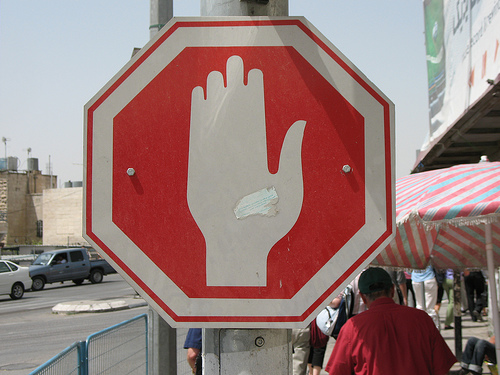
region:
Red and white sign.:
[66, 13, 401, 343]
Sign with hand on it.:
[89, 6, 419, 327]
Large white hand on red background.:
[182, 55, 312, 292]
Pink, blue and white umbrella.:
[366, 158, 498, 273]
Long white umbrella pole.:
[484, 228, 499, 367]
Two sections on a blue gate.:
[27, 313, 160, 373]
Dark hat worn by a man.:
[357, 269, 399, 297]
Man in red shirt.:
[322, 258, 452, 373]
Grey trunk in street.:
[21, 247, 117, 287]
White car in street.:
[0, 250, 34, 304]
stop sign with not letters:
[80, 14, 395, 331]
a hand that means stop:
[186, 56, 305, 286]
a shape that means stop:
[84, 15, 395, 329]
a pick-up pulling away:
[23, 247, 116, 292]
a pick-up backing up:
[27, 247, 118, 291]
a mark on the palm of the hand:
[234, 185, 279, 222]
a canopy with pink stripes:
[372, 161, 499, 271]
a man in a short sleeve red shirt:
[319, 266, 457, 373]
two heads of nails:
[122, 164, 354, 179]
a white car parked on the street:
[0, 261, 33, 300]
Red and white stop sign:
[72, 8, 403, 336]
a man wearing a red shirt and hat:
[324, 263, 460, 373]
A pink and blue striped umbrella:
[357, 161, 499, 373]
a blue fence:
[27, 308, 157, 373]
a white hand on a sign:
[164, 48, 324, 298]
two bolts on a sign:
[117, 161, 362, 183]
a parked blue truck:
[26, 243, 119, 293]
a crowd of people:
[386, 266, 491, 333]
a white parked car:
[0, 256, 32, 301]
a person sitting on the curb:
[449, 325, 498, 373]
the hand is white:
[199, 83, 294, 172]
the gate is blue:
[88, 311, 133, 358]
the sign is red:
[141, 207, 186, 247]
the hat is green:
[360, 265, 392, 292]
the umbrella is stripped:
[426, 175, 459, 198]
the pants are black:
[466, 337, 483, 360]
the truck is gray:
[43, 258, 63, 275]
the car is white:
[3, 271, 24, 288]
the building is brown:
[10, 184, 24, 205]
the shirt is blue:
[188, 333, 198, 348]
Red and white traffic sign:
[82, 17, 394, 329]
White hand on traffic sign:
[187, 54, 304, 286]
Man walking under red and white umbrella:
[326, 268, 456, 373]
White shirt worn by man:
[316, 305, 339, 334]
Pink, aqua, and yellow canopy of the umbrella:
[381, 164, 498, 269]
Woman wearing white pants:
[411, 279, 437, 308]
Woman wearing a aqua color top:
[410, 265, 435, 280]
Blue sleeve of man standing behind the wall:
[184, 328, 201, 349]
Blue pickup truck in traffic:
[27, 248, 110, 290]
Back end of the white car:
[1, 259, 32, 299]